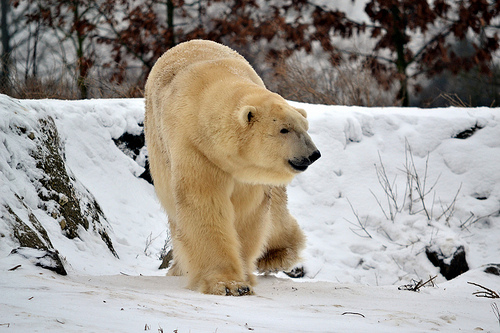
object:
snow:
[346, 155, 434, 244]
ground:
[85, 257, 303, 332]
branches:
[403, 133, 430, 220]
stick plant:
[341, 133, 487, 252]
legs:
[169, 155, 256, 296]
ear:
[238, 105, 258, 129]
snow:
[4, 97, 139, 235]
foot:
[198, 276, 254, 297]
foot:
[165, 262, 184, 276]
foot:
[245, 271, 259, 286]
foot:
[254, 247, 301, 277]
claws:
[237, 284, 247, 296]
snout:
[287, 140, 321, 172]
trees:
[325, 0, 498, 106]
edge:
[201, 283, 255, 297]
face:
[268, 109, 320, 173]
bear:
[143, 38, 321, 296]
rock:
[425, 244, 471, 281]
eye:
[279, 127, 290, 134]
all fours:
[165, 184, 306, 297]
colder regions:
[340, 39, 491, 175]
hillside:
[322, 95, 490, 178]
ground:
[335, 243, 474, 331]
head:
[231, 100, 322, 176]